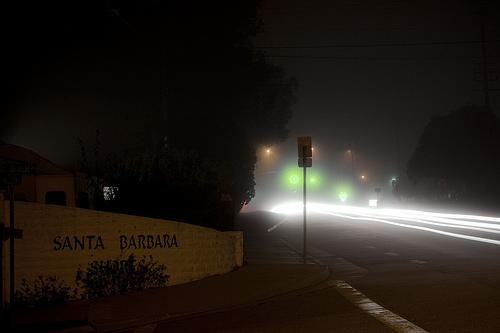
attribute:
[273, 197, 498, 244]
light — car 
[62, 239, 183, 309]
bush — little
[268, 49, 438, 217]
sky — dark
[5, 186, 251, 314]
sign — white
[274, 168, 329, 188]
lights — orange 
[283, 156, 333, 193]
lights — faded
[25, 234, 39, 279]
wall. — brick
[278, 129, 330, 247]
post — sign  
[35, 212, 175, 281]
wall — brick, white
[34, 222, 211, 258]
sant barbara — wall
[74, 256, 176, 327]
plants — small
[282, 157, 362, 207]
lights — green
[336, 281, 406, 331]
line — white, painted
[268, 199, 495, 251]
streaks — white 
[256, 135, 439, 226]
fog — night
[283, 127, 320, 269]
sign — tall 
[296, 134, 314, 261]
street sign — back 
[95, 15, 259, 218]
tree — big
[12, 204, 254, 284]
wall — white